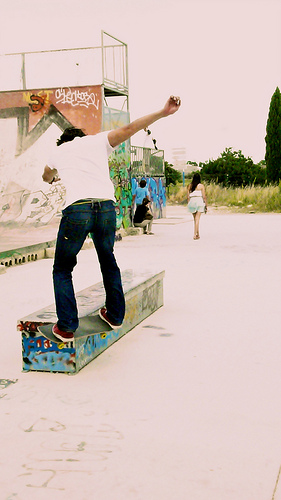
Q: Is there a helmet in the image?
A: No, there are no helmets.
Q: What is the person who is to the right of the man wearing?
A: The person is wearing a skirt.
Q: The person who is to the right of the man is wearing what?
A: The person is wearing a skirt.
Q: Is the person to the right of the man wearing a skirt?
A: Yes, the person is wearing a skirt.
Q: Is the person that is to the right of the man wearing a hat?
A: No, the person is wearing a skirt.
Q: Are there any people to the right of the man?
A: Yes, there is a person to the right of the man.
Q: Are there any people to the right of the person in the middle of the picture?
A: Yes, there is a person to the right of the man.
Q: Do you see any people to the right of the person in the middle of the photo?
A: Yes, there is a person to the right of the man.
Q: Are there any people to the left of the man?
A: No, the person is to the right of the man.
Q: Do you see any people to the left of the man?
A: No, the person is to the right of the man.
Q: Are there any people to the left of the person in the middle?
A: No, the person is to the right of the man.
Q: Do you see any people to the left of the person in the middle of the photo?
A: No, the person is to the right of the man.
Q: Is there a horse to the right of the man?
A: No, there is a person to the right of the man.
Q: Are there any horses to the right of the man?
A: No, there is a person to the right of the man.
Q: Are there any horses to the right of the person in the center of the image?
A: No, there is a person to the right of the man.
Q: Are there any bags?
A: No, there are no bags.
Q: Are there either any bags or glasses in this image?
A: No, there are no bags or glasses.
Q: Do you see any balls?
A: No, there are no balls.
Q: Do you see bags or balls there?
A: No, there are no balls or bags.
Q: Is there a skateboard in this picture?
A: Yes, there is a skateboard.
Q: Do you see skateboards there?
A: Yes, there is a skateboard.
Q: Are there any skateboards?
A: Yes, there is a skateboard.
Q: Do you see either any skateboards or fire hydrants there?
A: Yes, there is a skateboard.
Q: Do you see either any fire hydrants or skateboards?
A: Yes, there is a skateboard.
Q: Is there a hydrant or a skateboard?
A: Yes, there is a skateboard.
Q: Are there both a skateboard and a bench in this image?
A: No, there is a skateboard but no benches.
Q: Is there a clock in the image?
A: No, there are no clocks.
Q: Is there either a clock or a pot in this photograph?
A: No, there are no clocks or pots.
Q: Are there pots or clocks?
A: No, there are no clocks or pots.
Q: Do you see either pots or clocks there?
A: No, there are no clocks or pots.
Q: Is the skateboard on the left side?
A: Yes, the skateboard is on the left of the image.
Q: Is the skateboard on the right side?
A: No, the skateboard is on the left of the image.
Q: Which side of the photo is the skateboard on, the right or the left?
A: The skateboard is on the left of the image.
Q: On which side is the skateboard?
A: The skateboard is on the left of the image.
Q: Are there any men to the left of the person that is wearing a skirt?
A: Yes, there is a man to the left of the person.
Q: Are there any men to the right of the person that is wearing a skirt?
A: No, the man is to the left of the person.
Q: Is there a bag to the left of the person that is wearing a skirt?
A: No, there is a man to the left of the person.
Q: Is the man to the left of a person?
A: Yes, the man is to the left of a person.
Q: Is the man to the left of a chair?
A: No, the man is to the left of a person.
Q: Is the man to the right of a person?
A: No, the man is to the left of a person.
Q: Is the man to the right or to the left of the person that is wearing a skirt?
A: The man is to the left of the person.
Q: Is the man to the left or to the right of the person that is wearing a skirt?
A: The man is to the left of the person.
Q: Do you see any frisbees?
A: No, there are no frisbees.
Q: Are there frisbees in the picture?
A: No, there are no frisbees.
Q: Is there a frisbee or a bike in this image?
A: No, there are no frisbees or bikes.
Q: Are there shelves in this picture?
A: No, there are no shelves.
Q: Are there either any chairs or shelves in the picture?
A: No, there are no shelves or chairs.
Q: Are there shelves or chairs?
A: No, there are no shelves or chairs.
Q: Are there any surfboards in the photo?
A: No, there are no surfboards.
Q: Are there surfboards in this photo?
A: No, there are no surfboards.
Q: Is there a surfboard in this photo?
A: No, there are no surfboards.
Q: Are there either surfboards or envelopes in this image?
A: No, there are no surfboards or envelopes.